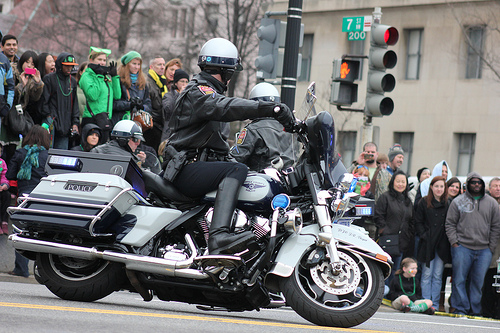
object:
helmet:
[194, 36, 243, 69]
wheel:
[270, 219, 395, 332]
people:
[34, 49, 84, 151]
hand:
[337, 59, 353, 79]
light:
[265, 190, 296, 213]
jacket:
[73, 64, 124, 122]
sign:
[336, 14, 367, 34]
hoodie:
[438, 172, 499, 254]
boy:
[379, 253, 440, 317]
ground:
[0, 269, 500, 333]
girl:
[73, 42, 126, 145]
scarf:
[145, 68, 170, 96]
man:
[140, 55, 173, 136]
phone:
[23, 70, 35, 79]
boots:
[204, 174, 257, 255]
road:
[0, 269, 500, 332]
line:
[0, 301, 418, 333]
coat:
[409, 193, 458, 269]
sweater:
[388, 274, 427, 301]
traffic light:
[364, 95, 397, 119]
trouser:
[157, 153, 252, 202]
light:
[328, 57, 361, 85]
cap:
[59, 53, 80, 67]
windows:
[450, 15, 496, 84]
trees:
[104, 0, 161, 60]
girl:
[405, 174, 459, 313]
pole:
[358, 124, 375, 187]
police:
[149, 29, 310, 254]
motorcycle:
[0, 32, 397, 327]